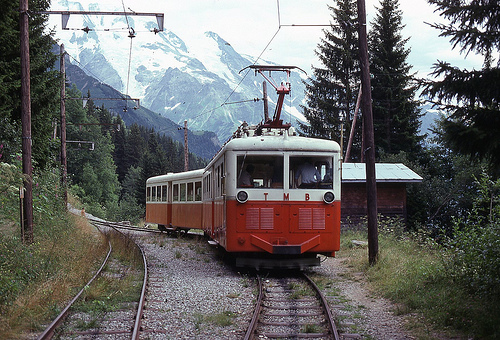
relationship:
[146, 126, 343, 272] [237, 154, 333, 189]
car has a train windshield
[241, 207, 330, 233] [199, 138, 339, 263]
vents are on front of train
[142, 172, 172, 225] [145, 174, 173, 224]
car on train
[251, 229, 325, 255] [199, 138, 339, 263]
bumper on train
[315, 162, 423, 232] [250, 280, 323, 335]
building near tracks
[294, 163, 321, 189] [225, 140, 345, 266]
man standing on train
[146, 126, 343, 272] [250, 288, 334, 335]
car on track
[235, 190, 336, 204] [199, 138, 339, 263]
headlights are on train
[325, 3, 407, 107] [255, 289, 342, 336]
pine tree along tracks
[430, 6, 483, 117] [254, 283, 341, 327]
pine tree along tracks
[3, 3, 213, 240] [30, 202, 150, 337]
fir trees along tracks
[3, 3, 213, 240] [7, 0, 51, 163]
fir trees along tracks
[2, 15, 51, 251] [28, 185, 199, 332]
electrical pole along track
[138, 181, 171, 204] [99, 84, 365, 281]
window on train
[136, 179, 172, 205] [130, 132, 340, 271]
window on train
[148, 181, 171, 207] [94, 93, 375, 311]
window on train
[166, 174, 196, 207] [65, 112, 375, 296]
window on train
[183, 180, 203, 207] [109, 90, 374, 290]
window on train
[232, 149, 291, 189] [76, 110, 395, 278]
window on train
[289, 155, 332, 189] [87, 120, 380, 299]
window on train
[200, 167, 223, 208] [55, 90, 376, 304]
window on train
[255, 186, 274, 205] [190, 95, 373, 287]
letter on train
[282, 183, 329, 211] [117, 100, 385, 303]
letter on train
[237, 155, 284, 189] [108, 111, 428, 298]
window of train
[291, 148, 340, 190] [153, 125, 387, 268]
window of train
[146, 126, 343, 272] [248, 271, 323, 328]
car driving on tracks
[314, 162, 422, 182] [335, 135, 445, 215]
roof of building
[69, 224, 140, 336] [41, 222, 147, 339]
weeds growing between tracks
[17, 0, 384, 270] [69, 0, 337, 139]
poles support electrical wires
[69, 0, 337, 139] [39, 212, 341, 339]
electrical wires above train tracks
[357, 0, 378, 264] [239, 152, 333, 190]
post visible behind train windshield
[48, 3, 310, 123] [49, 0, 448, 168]
snow on mountains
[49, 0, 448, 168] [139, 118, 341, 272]
mountains behind train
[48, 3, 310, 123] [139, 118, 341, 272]
snow behind train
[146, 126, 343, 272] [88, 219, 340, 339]
car on tracks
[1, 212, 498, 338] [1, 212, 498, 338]
ground on ground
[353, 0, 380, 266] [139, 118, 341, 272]
pole beside train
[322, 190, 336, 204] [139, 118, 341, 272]
headlights on train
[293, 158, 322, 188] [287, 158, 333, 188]
conductor in window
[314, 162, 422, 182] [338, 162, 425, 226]
roof on building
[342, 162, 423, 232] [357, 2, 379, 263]
building behind post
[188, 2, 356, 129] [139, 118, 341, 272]
cable above train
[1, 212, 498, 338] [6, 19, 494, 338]
ground in countryside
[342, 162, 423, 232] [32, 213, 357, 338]
building next to train track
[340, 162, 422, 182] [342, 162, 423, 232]
roof on a building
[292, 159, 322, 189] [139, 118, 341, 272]
man driving a train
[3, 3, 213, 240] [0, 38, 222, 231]
fir trees on a hillside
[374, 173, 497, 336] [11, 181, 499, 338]
bushes on a hillside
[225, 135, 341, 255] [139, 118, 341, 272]
front of a train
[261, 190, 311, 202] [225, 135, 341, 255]
letters on front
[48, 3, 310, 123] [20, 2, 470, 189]
snow on mountain